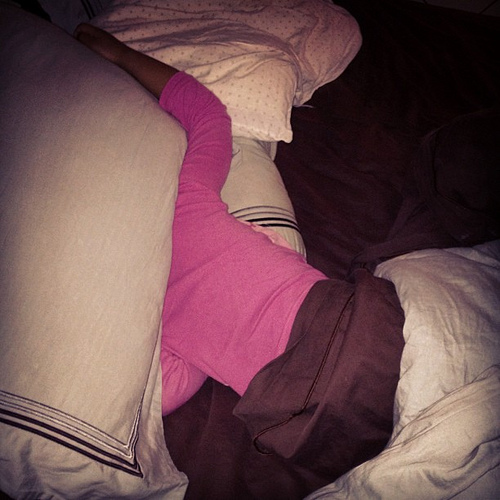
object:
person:
[73, 22, 500, 416]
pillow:
[2, 5, 187, 500]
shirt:
[158, 70, 324, 416]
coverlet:
[295, 237, 500, 499]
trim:
[235, 209, 304, 236]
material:
[93, 2, 363, 145]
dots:
[81, 3, 364, 143]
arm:
[72, 24, 231, 218]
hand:
[74, 24, 125, 55]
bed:
[0, 3, 498, 498]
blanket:
[232, 1, 497, 499]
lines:
[0, 389, 147, 483]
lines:
[231, 205, 300, 234]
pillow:
[0, 7, 309, 496]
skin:
[74, 23, 176, 99]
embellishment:
[224, 203, 304, 229]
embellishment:
[0, 390, 146, 477]